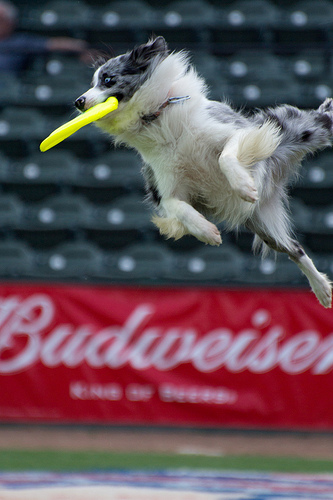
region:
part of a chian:
[170, 85, 185, 116]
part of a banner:
[237, 383, 269, 423]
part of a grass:
[105, 444, 132, 465]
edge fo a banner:
[239, 421, 257, 460]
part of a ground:
[192, 427, 209, 453]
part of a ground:
[238, 443, 260, 468]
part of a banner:
[237, 401, 264, 444]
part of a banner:
[267, 406, 280, 425]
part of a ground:
[219, 440, 239, 458]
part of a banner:
[257, 384, 285, 419]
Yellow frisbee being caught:
[28, 95, 122, 153]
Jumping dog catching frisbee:
[70, 31, 328, 315]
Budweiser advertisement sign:
[4, 296, 330, 381]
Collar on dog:
[135, 91, 194, 126]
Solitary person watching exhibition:
[4, 4, 96, 92]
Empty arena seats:
[7, 152, 155, 282]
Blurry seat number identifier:
[37, 208, 55, 223]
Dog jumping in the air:
[73, 33, 331, 310]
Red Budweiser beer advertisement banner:
[4, 277, 332, 435]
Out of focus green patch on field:
[3, 443, 330, 478]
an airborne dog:
[35, 38, 330, 300]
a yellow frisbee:
[32, 93, 115, 143]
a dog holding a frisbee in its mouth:
[20, 45, 132, 124]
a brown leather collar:
[139, 105, 154, 122]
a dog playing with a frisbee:
[36, 51, 325, 301]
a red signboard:
[44, 299, 313, 412]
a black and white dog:
[46, 45, 331, 278]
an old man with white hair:
[0, 2, 97, 81]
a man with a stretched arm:
[4, 10, 97, 68]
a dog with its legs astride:
[230, 88, 327, 283]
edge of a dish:
[66, 110, 85, 130]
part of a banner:
[227, 379, 251, 415]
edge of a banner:
[245, 415, 274, 439]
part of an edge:
[218, 416, 241, 451]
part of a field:
[201, 463, 217, 485]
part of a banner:
[175, 377, 214, 443]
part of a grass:
[208, 454, 220, 473]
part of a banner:
[248, 387, 274, 427]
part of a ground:
[177, 434, 196, 451]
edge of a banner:
[239, 405, 258, 430]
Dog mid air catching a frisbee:
[39, 38, 331, 310]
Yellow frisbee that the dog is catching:
[36, 95, 117, 152]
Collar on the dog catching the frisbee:
[139, 93, 187, 119]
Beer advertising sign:
[1, 284, 331, 424]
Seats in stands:
[1, 1, 332, 285]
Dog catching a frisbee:
[39, 35, 331, 299]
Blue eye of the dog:
[100, 69, 114, 84]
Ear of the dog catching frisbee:
[125, 35, 166, 72]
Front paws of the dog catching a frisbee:
[173, 162, 259, 246]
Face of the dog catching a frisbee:
[38, 37, 165, 153]